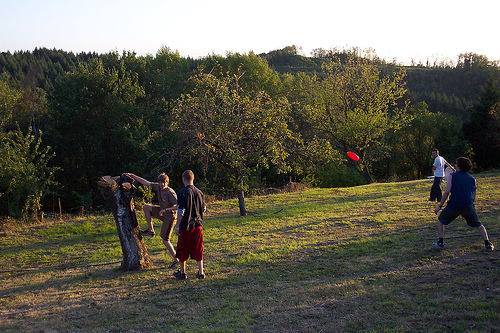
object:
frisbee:
[346, 151, 360, 161]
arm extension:
[438, 171, 455, 206]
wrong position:
[123, 171, 175, 266]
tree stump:
[102, 170, 147, 271]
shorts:
[175, 229, 208, 265]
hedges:
[218, 161, 353, 185]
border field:
[7, 179, 376, 229]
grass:
[261, 211, 282, 224]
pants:
[425, 179, 443, 206]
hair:
[158, 173, 169, 183]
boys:
[439, 158, 481, 244]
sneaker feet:
[483, 242, 494, 251]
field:
[0, 281, 487, 320]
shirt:
[427, 157, 447, 182]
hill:
[11, 50, 487, 161]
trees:
[319, 60, 416, 185]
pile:
[278, 182, 312, 192]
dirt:
[289, 184, 305, 192]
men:
[176, 168, 207, 279]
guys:
[145, 173, 178, 266]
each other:
[177, 170, 209, 279]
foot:
[142, 221, 156, 237]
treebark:
[99, 172, 153, 271]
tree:
[185, 68, 291, 209]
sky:
[7, 5, 486, 47]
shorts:
[152, 204, 177, 238]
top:
[449, 156, 469, 175]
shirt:
[152, 187, 177, 223]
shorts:
[435, 199, 482, 228]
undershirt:
[174, 208, 184, 217]